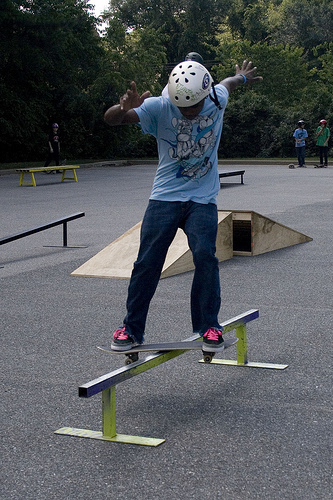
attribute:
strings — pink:
[201, 329, 223, 343]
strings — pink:
[112, 327, 132, 341]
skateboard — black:
[100, 344, 232, 361]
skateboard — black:
[291, 162, 295, 169]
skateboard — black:
[311, 161, 326, 169]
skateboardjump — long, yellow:
[18, 160, 82, 185]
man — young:
[293, 118, 309, 164]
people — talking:
[274, 104, 322, 136]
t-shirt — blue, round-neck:
[131, 83, 228, 205]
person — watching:
[113, 50, 221, 247]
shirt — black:
[47, 131, 60, 147]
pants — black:
[41, 148, 61, 166]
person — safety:
[315, 118, 332, 167]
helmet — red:
[316, 117, 331, 127]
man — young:
[105, 57, 263, 353]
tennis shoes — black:
[111, 330, 313, 353]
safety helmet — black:
[296, 120, 304, 124]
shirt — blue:
[135, 85, 230, 208]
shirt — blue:
[292, 128, 308, 147]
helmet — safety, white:
[165, 60, 213, 107]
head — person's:
[161, 61, 213, 120]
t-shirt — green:
[315, 126, 331, 146]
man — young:
[45, 121, 63, 174]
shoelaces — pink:
[202, 328, 222, 343]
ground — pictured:
[1, 167, 329, 498]